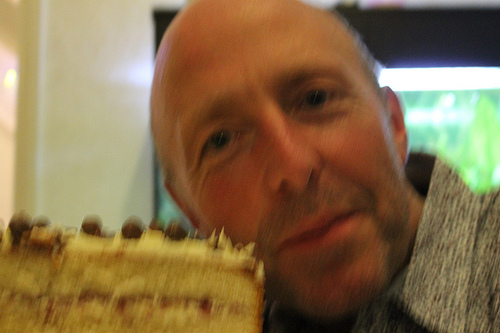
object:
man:
[150, 0, 500, 333]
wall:
[41, 2, 143, 216]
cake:
[2, 213, 267, 333]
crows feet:
[179, 53, 352, 151]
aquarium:
[379, 66, 499, 190]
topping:
[2, 212, 249, 265]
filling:
[6, 285, 234, 317]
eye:
[290, 79, 348, 115]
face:
[170, 23, 399, 314]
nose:
[261, 117, 322, 192]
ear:
[379, 86, 408, 165]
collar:
[395, 148, 477, 333]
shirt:
[264, 153, 500, 333]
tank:
[376, 64, 500, 190]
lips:
[275, 205, 364, 254]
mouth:
[275, 205, 370, 258]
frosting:
[3, 219, 253, 264]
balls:
[81, 212, 190, 241]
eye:
[198, 125, 245, 165]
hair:
[256, 183, 411, 317]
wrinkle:
[185, 165, 211, 201]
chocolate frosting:
[23, 276, 239, 326]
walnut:
[8, 211, 34, 241]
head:
[149, 9, 408, 318]